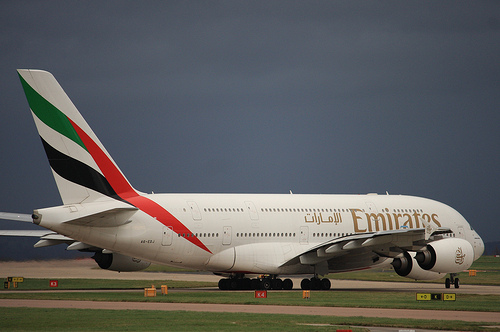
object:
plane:
[0, 69, 485, 292]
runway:
[0, 253, 499, 330]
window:
[237, 233, 239, 238]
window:
[313, 233, 315, 237]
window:
[309, 208, 312, 211]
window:
[212, 208, 215, 212]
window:
[385, 207, 389, 212]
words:
[303, 208, 441, 233]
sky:
[0, 0, 498, 254]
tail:
[17, 69, 137, 250]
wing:
[277, 227, 453, 275]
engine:
[414, 237, 475, 273]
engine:
[390, 251, 448, 281]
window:
[470, 226, 473, 230]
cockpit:
[470, 225, 474, 230]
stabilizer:
[14, 65, 148, 209]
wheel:
[454, 278, 460, 288]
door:
[161, 225, 174, 246]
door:
[222, 225, 232, 246]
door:
[185, 200, 203, 222]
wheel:
[445, 278, 450, 289]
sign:
[416, 293, 456, 300]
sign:
[254, 290, 267, 298]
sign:
[302, 290, 309, 299]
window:
[277, 233, 280, 237]